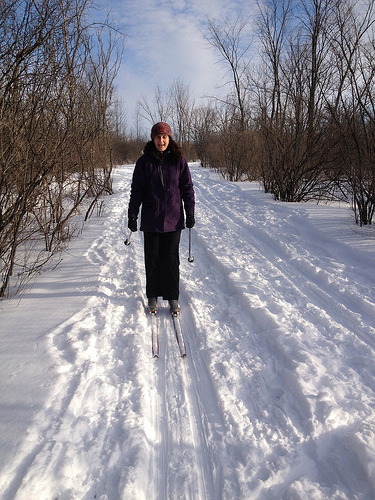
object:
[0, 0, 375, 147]
cloud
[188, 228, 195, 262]
pole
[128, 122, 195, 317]
skier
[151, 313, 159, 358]
ski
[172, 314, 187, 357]
ski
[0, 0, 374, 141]
sky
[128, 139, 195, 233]
coat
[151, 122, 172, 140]
hat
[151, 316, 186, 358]
skis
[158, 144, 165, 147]
mouth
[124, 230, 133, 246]
ski sticks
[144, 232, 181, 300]
pants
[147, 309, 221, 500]
ski tracks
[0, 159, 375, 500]
snow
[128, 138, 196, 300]
outfit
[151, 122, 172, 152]
head